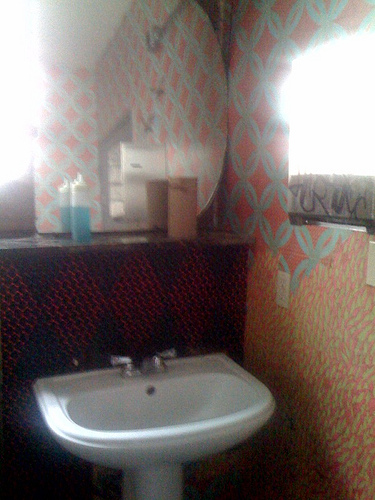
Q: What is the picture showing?
A: It is showing a bathroom.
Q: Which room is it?
A: It is a bathroom.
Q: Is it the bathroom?
A: Yes, it is the bathroom.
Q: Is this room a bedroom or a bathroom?
A: It is a bathroom.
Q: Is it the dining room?
A: No, it is the bathroom.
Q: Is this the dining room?
A: No, it is the bathroom.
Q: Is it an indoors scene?
A: Yes, it is indoors.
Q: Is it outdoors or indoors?
A: It is indoors.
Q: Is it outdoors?
A: No, it is indoors.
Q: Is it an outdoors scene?
A: No, it is indoors.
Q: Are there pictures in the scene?
A: No, there are no pictures.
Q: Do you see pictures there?
A: No, there are no pictures.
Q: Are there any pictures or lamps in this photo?
A: No, there are no pictures or lamps.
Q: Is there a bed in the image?
A: No, there are no beds.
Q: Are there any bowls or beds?
A: No, there are no beds or bowls.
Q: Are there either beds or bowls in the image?
A: No, there are no beds or bowls.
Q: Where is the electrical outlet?
A: The electrical outlet is in the bathroom.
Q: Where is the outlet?
A: The electrical outlet is in the bathroom.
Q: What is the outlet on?
A: The outlet is on the wall.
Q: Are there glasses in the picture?
A: No, there are no glasses.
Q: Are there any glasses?
A: No, there are no glasses.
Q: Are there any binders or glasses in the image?
A: No, there are no glasses or binders.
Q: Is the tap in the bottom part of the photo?
A: Yes, the tap is in the bottom of the image.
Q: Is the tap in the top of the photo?
A: No, the tap is in the bottom of the image.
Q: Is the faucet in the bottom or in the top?
A: The faucet is in the bottom of the image.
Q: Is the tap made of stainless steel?
A: Yes, the tap is made of stainless steel.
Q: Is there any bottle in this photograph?
A: Yes, there is a bottle.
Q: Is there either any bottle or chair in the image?
A: Yes, there is a bottle.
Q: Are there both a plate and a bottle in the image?
A: No, there is a bottle but no plates.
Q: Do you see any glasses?
A: No, there are no glasses.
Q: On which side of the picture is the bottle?
A: The bottle is on the left of the image.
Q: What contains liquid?
A: The bottle contains liquid.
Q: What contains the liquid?
A: The bottle contains liquid.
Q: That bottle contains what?
A: The bottle contains liquid.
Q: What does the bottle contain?
A: The bottle contains liquid.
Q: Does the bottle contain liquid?
A: Yes, the bottle contains liquid.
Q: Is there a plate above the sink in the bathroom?
A: No, there is a bottle above the sink.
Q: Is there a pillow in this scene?
A: No, there are no pillows.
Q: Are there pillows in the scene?
A: No, there are no pillows.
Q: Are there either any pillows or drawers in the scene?
A: No, there are no pillows or drawers.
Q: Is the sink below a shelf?
A: No, the sink is below the bottle.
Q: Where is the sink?
A: The sink is in the bathroom.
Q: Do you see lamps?
A: No, there are no lamps.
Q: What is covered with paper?
A: The wall is covered with paper.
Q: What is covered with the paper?
A: The wall is covered with paper.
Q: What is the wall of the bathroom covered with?
A: The wall is covered with paper.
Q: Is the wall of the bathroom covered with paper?
A: Yes, the wall is covered with paper.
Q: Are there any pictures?
A: No, there are no pictures.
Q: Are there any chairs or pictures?
A: No, there are no pictures or chairs.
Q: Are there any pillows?
A: No, there are no pillows.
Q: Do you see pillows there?
A: No, there are no pillows.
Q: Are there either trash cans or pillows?
A: No, there are no pillows or trash cans.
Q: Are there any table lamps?
A: No, there are no table lamps.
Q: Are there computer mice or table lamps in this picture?
A: No, there are no table lamps or computer mice.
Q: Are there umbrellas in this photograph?
A: No, there are no umbrellas.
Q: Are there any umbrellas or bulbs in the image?
A: No, there are no umbrellas or bulbs.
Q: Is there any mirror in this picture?
A: Yes, there is a mirror.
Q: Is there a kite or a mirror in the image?
A: Yes, there is a mirror.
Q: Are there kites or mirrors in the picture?
A: Yes, there is a mirror.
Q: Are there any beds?
A: No, there are no beds.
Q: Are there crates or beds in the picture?
A: No, there are no beds or crates.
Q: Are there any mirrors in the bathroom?
A: Yes, there is a mirror in the bathroom.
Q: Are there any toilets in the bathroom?
A: No, there is a mirror in the bathroom.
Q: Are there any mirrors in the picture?
A: Yes, there is a mirror.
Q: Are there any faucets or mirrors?
A: Yes, there is a mirror.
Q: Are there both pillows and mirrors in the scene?
A: No, there is a mirror but no pillows.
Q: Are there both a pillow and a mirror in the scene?
A: No, there is a mirror but no pillows.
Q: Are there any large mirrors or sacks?
A: Yes, there is a large mirror.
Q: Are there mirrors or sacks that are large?
A: Yes, the mirror is large.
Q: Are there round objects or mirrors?
A: Yes, there is a round mirror.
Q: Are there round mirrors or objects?
A: Yes, there is a round mirror.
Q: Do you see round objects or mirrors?
A: Yes, there is a round mirror.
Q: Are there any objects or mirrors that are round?
A: Yes, the mirror is round.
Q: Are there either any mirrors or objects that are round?
A: Yes, the mirror is round.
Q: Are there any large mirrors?
A: Yes, there is a large mirror.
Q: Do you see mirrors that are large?
A: Yes, there is a mirror that is large.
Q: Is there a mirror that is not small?
A: Yes, there is a large mirror.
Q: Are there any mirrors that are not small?
A: Yes, there is a large mirror.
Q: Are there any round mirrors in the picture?
A: Yes, there is a round mirror.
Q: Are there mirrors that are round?
A: Yes, there is a mirror that is round.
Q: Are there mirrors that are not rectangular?
A: Yes, there is a round mirror.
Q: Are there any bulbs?
A: No, there are no bulbs.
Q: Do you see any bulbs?
A: No, there are no bulbs.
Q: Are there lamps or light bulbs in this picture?
A: No, there are no light bulbs or lamps.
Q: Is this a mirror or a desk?
A: This is a mirror.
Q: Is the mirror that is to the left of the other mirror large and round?
A: Yes, the mirror is large and round.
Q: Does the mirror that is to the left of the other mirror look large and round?
A: Yes, the mirror is large and round.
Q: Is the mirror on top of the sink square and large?
A: No, the mirror is large but round.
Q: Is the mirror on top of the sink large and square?
A: No, the mirror is large but round.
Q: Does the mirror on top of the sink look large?
A: Yes, the mirror is large.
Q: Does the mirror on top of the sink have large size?
A: Yes, the mirror is large.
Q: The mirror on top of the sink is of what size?
A: The mirror is large.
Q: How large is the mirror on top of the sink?
A: The mirror is large.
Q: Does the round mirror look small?
A: No, the mirror is large.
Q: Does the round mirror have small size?
A: No, the mirror is large.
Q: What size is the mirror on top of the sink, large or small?
A: The mirror is large.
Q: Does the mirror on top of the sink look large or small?
A: The mirror is large.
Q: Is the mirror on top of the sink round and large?
A: Yes, the mirror is round and large.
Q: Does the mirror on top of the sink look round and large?
A: Yes, the mirror is round and large.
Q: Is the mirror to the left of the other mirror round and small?
A: No, the mirror is round but large.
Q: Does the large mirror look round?
A: Yes, the mirror is round.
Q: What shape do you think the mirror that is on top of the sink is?
A: The mirror is round.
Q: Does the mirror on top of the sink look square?
A: No, the mirror is round.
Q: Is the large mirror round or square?
A: The mirror is round.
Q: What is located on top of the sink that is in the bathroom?
A: The mirror is on top of the sink.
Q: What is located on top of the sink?
A: The mirror is on top of the sink.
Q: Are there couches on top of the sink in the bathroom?
A: No, there is a mirror on top of the sink.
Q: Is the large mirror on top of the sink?
A: Yes, the mirror is on top of the sink.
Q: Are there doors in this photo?
A: Yes, there is a door.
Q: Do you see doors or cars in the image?
A: Yes, there is a door.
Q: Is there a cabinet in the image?
A: No, there are no cabinets.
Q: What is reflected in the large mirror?
A: The door is reflected in the mirror.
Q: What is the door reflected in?
A: The door is reflected in the mirror.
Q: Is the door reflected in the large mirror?
A: Yes, the door is reflected in the mirror.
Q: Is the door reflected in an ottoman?
A: No, the door is reflected in the mirror.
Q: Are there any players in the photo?
A: No, there are no players.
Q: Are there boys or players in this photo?
A: No, there are no players or boys.